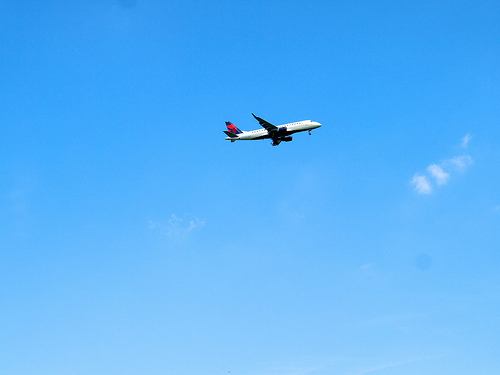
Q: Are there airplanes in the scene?
A: Yes, there is an airplane.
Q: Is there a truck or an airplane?
A: Yes, there is an airplane.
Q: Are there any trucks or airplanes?
A: Yes, there is an airplane.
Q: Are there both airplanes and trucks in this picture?
A: No, there is an airplane but no trucks.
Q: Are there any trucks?
A: No, there are no trucks.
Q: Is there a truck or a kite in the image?
A: No, there are no trucks or kites.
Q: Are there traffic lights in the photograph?
A: No, there are no traffic lights.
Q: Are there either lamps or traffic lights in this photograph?
A: No, there are no traffic lights or lamps.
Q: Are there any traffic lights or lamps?
A: No, there are no traffic lights or lamps.